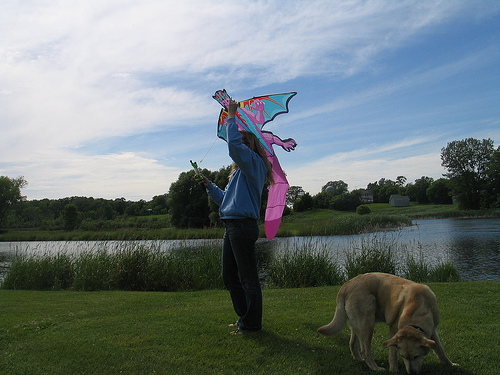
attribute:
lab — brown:
[318, 273, 464, 373]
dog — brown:
[318, 270, 461, 374]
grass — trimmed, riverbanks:
[0, 287, 498, 374]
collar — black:
[400, 324, 434, 340]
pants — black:
[219, 215, 265, 332]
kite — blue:
[212, 88, 298, 241]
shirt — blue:
[208, 115, 269, 219]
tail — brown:
[318, 297, 348, 335]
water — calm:
[1, 216, 499, 285]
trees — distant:
[1, 139, 499, 230]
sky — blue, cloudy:
[0, 0, 499, 204]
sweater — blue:
[207, 117, 269, 222]